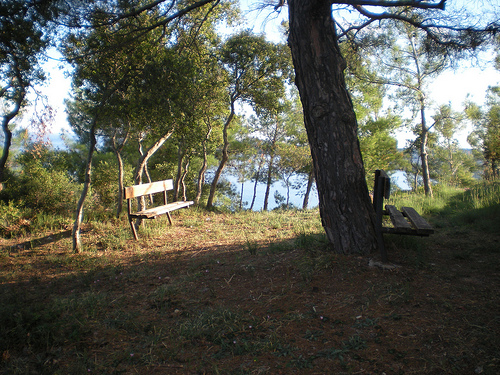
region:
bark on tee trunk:
[307, 105, 357, 179]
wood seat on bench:
[129, 197, 201, 232]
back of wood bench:
[119, 172, 184, 203]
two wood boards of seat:
[387, 199, 434, 238]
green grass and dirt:
[187, 271, 288, 338]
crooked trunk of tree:
[204, 109, 239, 184]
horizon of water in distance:
[376, 133, 461, 169]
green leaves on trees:
[227, 30, 292, 112]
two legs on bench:
[124, 212, 184, 246]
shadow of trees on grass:
[427, 188, 472, 220]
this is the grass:
[57, 268, 140, 360]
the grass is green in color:
[22, 308, 67, 350]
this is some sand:
[162, 237, 214, 280]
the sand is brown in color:
[170, 238, 209, 269]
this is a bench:
[377, 169, 434, 249]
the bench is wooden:
[382, 174, 424, 224]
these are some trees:
[8, 10, 490, 225]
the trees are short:
[217, 35, 279, 209]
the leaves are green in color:
[149, 60, 201, 102]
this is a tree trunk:
[304, 67, 374, 247]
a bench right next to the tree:
[373, 167, 422, 234]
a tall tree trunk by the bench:
[277, 0, 384, 254]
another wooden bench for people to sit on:
[120, 176, 193, 234]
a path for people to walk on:
[178, 202, 303, 367]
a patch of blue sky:
[423, 75, 490, 106]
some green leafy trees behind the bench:
[61, 15, 222, 255]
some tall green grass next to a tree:
[398, 184, 491, 251]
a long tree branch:
[353, 7, 499, 64]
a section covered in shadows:
[0, 240, 490, 374]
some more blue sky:
[43, 82, 69, 146]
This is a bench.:
[111, 165, 205, 241]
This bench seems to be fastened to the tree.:
[348, 151, 461, 273]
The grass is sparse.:
[85, 229, 299, 370]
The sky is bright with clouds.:
[379, 18, 496, 138]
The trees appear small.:
[91, 10, 385, 154]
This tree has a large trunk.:
[268, 8, 407, 270]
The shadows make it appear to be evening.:
[146, 128, 378, 258]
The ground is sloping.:
[89, 93, 409, 370]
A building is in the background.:
[378, 128, 498, 205]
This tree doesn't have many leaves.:
[380, 18, 464, 203]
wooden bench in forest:
[119, 177, 196, 242]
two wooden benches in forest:
[118, 168, 433, 247]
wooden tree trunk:
[283, 31, 376, 257]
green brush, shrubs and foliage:
[4, 153, 130, 230]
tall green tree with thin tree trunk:
[61, 32, 168, 258]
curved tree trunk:
[1, 45, 28, 176]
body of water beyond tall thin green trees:
[226, 166, 318, 208]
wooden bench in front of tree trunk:
[371, 170, 436, 260]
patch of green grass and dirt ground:
[191, 217, 241, 242]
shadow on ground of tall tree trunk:
[0, 230, 72, 253]